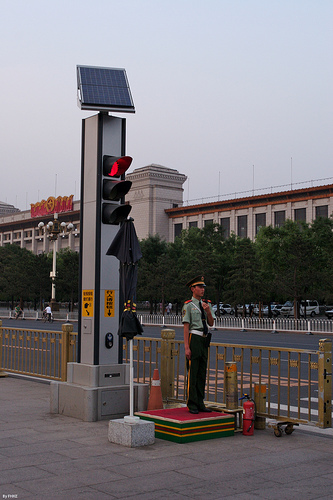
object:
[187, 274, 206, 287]
hat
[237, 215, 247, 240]
window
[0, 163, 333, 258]
building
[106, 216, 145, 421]
umbrella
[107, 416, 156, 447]
cement block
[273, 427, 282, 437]
wheels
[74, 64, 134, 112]
solar panel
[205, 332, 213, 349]
walkie talkie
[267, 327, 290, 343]
ground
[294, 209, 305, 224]
window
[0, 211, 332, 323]
trees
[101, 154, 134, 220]
light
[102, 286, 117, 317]
sign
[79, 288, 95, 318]
sign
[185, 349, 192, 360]
hands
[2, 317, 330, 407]
street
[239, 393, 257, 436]
fire extinguisher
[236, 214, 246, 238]
window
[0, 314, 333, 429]
fence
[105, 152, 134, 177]
signal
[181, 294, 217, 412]
uniform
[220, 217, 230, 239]
window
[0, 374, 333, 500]
sidewalk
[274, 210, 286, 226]
window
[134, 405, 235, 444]
podium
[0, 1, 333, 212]
sky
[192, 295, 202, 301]
neck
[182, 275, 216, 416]
posture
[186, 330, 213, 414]
pants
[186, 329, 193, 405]
stripe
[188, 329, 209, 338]
belt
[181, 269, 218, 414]
guard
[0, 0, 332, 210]
clouds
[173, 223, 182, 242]
window